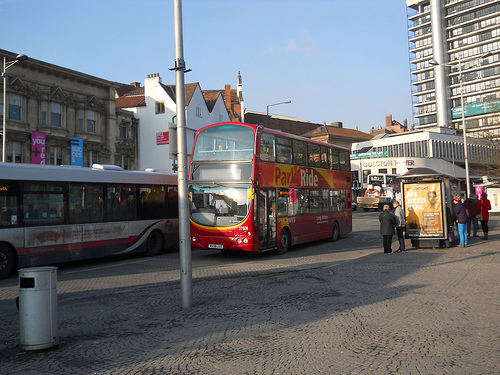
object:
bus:
[188, 120, 352, 254]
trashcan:
[16, 267, 62, 349]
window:
[193, 193, 247, 216]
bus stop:
[396, 168, 461, 247]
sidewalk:
[365, 245, 500, 371]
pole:
[177, 165, 195, 308]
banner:
[30, 132, 47, 164]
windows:
[271, 190, 343, 209]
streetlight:
[0, 52, 30, 156]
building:
[408, 4, 499, 138]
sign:
[448, 99, 500, 119]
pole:
[463, 123, 470, 201]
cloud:
[281, 38, 316, 55]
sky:
[68, 16, 152, 78]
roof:
[300, 126, 374, 140]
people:
[451, 195, 472, 248]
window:
[192, 132, 253, 159]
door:
[252, 185, 277, 247]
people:
[98, 189, 142, 220]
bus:
[0, 163, 178, 277]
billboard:
[274, 164, 321, 189]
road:
[147, 206, 386, 282]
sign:
[403, 184, 449, 243]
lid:
[19, 265, 60, 292]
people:
[287, 187, 335, 217]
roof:
[188, 81, 238, 127]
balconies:
[454, 27, 498, 71]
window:
[41, 100, 69, 134]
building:
[1, 48, 137, 172]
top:
[253, 123, 354, 170]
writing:
[407, 190, 424, 206]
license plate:
[205, 242, 225, 248]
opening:
[18, 272, 38, 287]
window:
[317, 147, 331, 168]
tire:
[276, 224, 293, 254]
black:
[283, 235, 289, 246]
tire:
[332, 220, 344, 241]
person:
[378, 204, 398, 253]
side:
[393, 167, 459, 242]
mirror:
[246, 188, 257, 200]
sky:
[220, 4, 390, 140]